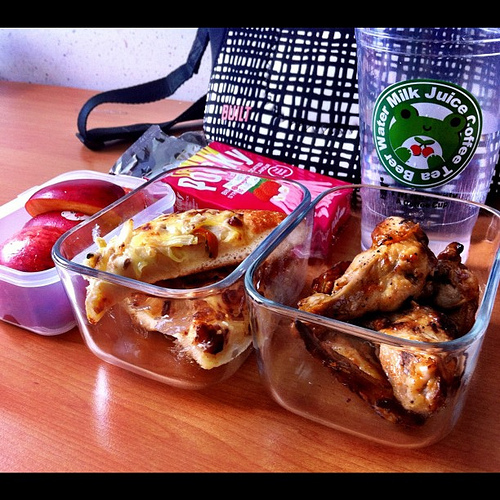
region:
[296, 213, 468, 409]
Cooked chicken wings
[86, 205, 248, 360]
Pizza slices inside a glass container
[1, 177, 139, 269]
Red apple slices inside a plastic container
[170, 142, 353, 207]
Red box of Pocky snacks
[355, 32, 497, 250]
Plastic tumbler glass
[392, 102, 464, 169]
Icon with green animal holding two small fruits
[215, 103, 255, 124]
Word "Built" written on lunch bag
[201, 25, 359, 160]
Lunch bag with white background and black criss-crossing lines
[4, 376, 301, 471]
Wooden counter top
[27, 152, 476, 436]
food inside of containers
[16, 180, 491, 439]
tasty food in containers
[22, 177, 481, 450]
some tasty food in containers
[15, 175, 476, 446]
good food in containers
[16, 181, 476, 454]
well cooked food in containers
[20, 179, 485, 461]
well seasoned food in containers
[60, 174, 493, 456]
flavorful food in containers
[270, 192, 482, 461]
tasty chicken in containers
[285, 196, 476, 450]
good chicken in containers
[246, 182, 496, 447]
Glass container on the table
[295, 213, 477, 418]
Chicken pieces in the glass container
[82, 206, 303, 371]
Pizza in the glass container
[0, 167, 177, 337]
Plastic container on the table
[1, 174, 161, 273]
Apple slices in the plastic container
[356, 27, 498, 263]
Cup on the table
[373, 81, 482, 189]
Picture on the cup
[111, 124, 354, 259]
Red box on the table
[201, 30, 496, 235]
Bag on the table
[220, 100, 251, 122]
Pink letters on the bag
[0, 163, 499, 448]
Three small food containers.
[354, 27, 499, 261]
A plastic drinking cup.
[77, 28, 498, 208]
A black and white bag.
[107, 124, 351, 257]
A box of Pocky Sticks.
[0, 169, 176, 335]
A small container of apple slices.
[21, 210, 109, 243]
A sticker on the apple slice.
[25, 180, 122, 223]
The flesh of the apple is turning brown.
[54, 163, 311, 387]
A container with two small pieces of pizza.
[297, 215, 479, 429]
Chicken wings and drumsticks in a container.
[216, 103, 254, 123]
The word "BUILT" in pink lettering.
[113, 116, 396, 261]
red box of juice on table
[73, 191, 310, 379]
pieces of pizza in container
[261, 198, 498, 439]
bbq chicken wings in container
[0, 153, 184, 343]
apple pieces in plastic container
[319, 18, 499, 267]
plastic empty cup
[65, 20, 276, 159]
black bag strap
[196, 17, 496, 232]
black and white bag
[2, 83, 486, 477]
brown wooden table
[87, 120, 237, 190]
silver satchet on table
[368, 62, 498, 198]
green emblem on cup